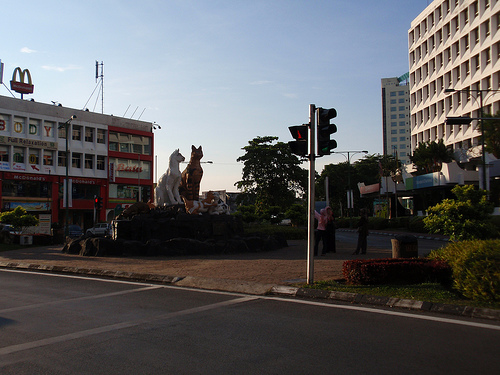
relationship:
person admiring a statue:
[312, 204, 331, 260] [145, 141, 210, 209]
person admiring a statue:
[320, 201, 345, 259] [145, 141, 210, 209]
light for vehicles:
[311, 101, 343, 158] [79, 220, 115, 240]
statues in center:
[128, 110, 283, 257] [90, 201, 310, 252]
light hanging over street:
[286, 123, 309, 141] [328, 214, 456, 264]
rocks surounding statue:
[58, 232, 294, 258] [178, 142, 208, 212]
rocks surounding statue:
[58, 232, 294, 258] [151, 147, 185, 208]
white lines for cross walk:
[109, 278, 251, 314] [10, 261, 280, 356]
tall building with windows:
[395, 10, 486, 175] [390, 89, 409, 149]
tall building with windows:
[395, 10, 486, 175] [419, 18, 459, 51]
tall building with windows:
[395, 10, 486, 175] [64, 111, 139, 167]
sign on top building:
[93, 56, 116, 107] [17, 58, 157, 228]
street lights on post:
[440, 80, 498, 135] [473, 86, 494, 196]